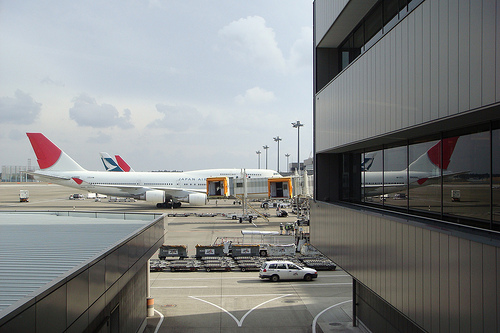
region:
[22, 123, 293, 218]
white plane with red tail wing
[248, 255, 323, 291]
a white car on the ground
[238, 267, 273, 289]
shadow cast behind white car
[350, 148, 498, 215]
reflection of plane in window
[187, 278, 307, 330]
white triangle on the ground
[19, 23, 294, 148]
white puffy clouds in the sky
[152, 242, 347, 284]
a line of luggage carts ready to use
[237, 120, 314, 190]
four tall light poles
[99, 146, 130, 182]
blue and white tail wing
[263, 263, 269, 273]
red tail light on white car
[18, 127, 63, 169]
Tip of plane's tail is red.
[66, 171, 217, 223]
Large white wing on side of plane.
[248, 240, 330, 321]
White car driving near airport.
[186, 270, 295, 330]
White lines marking road.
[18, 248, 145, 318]
Gray top on building.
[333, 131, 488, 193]
Large windows on side of building.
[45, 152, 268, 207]
Large white airplane sitting near airport.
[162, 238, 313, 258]
Gray luggage carrier near white car.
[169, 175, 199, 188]
Japan written on side of plane.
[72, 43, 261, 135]
Large clouds in sky.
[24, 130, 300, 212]
an airplane parked at the airport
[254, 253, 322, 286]
a vehicle parked on the ground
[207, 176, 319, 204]
a ramp to the airplane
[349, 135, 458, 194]
the airplane reflection in the window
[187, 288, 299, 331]
a white triangle on the pavement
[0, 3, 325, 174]
dark clouds in the sky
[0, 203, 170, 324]
the roof of a building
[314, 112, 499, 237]
windows on the side of a building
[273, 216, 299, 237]
workers on the ground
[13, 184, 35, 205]
a truck on the ground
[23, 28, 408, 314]
airplanes parked at the airport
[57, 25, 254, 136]
grey skies with grey and white clouds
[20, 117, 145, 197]
red or blue tails of three separate planes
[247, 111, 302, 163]
lighting on tall poles by planes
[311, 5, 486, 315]
dark building with panels and windows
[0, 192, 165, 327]
flat roof of low building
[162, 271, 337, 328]
white shape and lines on gray ground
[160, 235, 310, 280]
white vehicle in front of carts and haulers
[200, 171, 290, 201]
square orange openings on side of plane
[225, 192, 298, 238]
people and equipment on the ground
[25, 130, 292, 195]
white and red airplane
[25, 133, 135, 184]
red tips of airplane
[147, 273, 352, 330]
white markings on parking lot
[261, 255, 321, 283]
white car driving in lot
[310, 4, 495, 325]
building on the right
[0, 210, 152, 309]
white roof of building on left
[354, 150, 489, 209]
plane's reflection in the window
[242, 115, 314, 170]
tall light fixtures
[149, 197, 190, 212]
wheels on the airplane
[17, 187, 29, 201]
vehicle in the background